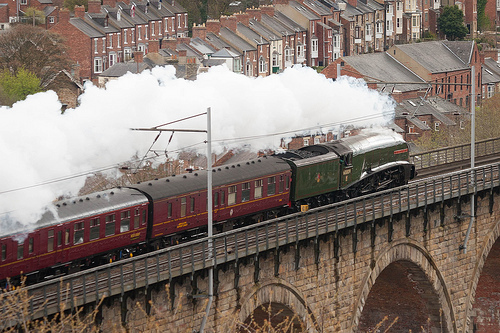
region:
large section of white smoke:
[235, 74, 411, 139]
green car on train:
[295, 147, 431, 177]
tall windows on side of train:
[141, 185, 229, 228]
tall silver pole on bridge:
[142, 103, 231, 259]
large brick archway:
[338, 235, 493, 322]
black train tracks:
[428, 142, 481, 182]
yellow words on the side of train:
[171, 211, 225, 241]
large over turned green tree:
[14, 30, 116, 105]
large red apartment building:
[71, 21, 243, 92]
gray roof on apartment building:
[377, 31, 443, 104]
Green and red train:
[2, 113, 425, 286]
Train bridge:
[395, 136, 497, 327]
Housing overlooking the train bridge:
[49, 8, 328, 63]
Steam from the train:
[36, 65, 366, 146]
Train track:
[416, 161, 456, 171]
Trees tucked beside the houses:
[7, 28, 46, 96]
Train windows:
[71, 212, 102, 247]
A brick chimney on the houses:
[53, 2, 71, 22]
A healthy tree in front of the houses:
[432, 1, 467, 36]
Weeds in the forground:
[5, 277, 406, 328]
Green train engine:
[238, 108, 435, 245]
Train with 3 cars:
[4, 86, 424, 326]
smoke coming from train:
[241, 55, 417, 172]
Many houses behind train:
[39, 1, 485, 193]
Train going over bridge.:
[137, 139, 497, 300]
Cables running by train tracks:
[120, 99, 495, 275]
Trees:
[0, 23, 86, 107]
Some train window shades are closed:
[209, 149, 339, 246]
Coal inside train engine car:
[265, 123, 420, 215]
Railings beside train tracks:
[389, 98, 499, 231]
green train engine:
[287, 125, 415, 200]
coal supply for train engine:
[283, 142, 332, 162]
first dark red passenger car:
[133, 153, 295, 237]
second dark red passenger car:
[3, 184, 148, 274]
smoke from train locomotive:
[1, 62, 398, 226]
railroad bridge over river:
[2, 142, 498, 331]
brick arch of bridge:
[350, 235, 458, 329]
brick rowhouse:
[45, 5, 107, 80]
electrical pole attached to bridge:
[129, 105, 215, 330]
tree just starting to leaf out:
[0, 19, 75, 79]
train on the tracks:
[22, 105, 409, 286]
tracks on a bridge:
[420, 128, 490, 228]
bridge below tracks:
[293, 206, 480, 331]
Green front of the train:
[293, 124, 416, 211]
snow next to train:
[66, 73, 249, 167]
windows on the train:
[2, 161, 287, 290]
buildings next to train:
[99, 3, 406, 73]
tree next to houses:
[0, 59, 48, 101]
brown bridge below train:
[293, 230, 463, 316]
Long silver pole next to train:
[188, 88, 225, 273]